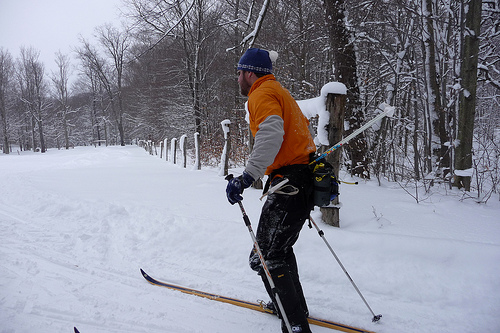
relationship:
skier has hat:
[186, 45, 370, 332] [238, 48, 273, 77]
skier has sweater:
[186, 45, 370, 332] [245, 77, 315, 174]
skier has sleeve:
[186, 45, 370, 332] [247, 117, 282, 183]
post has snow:
[315, 82, 351, 228] [322, 80, 344, 96]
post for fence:
[315, 82, 351, 228] [125, 126, 353, 196]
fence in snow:
[125, 126, 353, 196] [112, 148, 469, 313]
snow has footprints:
[112, 148, 469, 313] [124, 214, 207, 283]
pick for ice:
[322, 101, 407, 159] [377, 102, 395, 123]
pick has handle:
[322, 101, 407, 159] [267, 177, 293, 196]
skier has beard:
[186, 45, 370, 332] [239, 74, 251, 96]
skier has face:
[186, 45, 370, 332] [231, 65, 263, 96]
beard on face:
[239, 74, 251, 96] [231, 65, 263, 96]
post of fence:
[311, 82, 354, 127] [128, 86, 339, 222]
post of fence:
[186, 119, 206, 180] [128, 86, 339, 222]